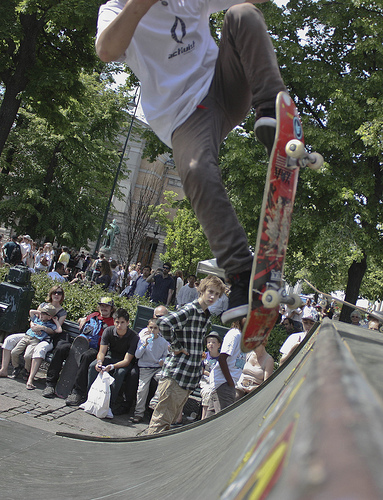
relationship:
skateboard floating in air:
[231, 89, 325, 354] [1, 0, 381, 499]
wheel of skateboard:
[284, 135, 308, 162] [231, 89, 325, 354]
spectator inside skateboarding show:
[0, 284, 70, 392] [1, 1, 381, 500]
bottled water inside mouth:
[145, 330, 156, 353] [148, 332, 156, 336]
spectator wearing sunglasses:
[0, 284, 70, 392] [48, 287, 66, 297]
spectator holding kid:
[0, 284, 70, 392] [10, 301, 63, 380]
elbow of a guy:
[92, 31, 128, 64] [91, 0, 308, 354]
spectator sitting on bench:
[0, 284, 70, 392] [48, 314, 220, 398]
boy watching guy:
[143, 272, 225, 436] [91, 0, 308, 354]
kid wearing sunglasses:
[10, 301, 63, 380] [35, 309, 53, 319]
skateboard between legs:
[231, 89, 325, 354] [171, 1, 292, 324]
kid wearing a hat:
[10, 301, 63, 380] [40, 298, 59, 319]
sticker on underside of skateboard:
[291, 114, 305, 140] [231, 89, 325, 354]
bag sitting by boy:
[78, 369, 118, 420] [130, 317, 170, 426]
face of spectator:
[48, 286, 66, 304] [0, 284, 70, 392]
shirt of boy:
[152, 301, 214, 393] [143, 272, 225, 436]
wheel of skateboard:
[259, 285, 281, 311] [231, 89, 325, 354]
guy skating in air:
[91, 0, 308, 354] [1, 0, 381, 499]